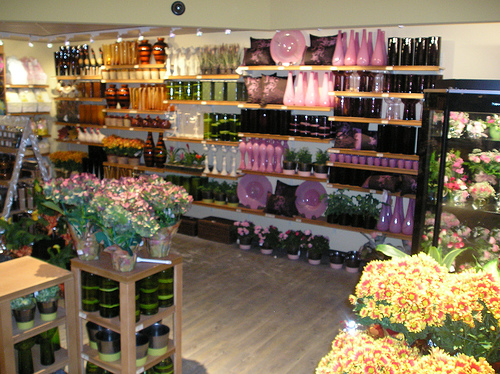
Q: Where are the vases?
A: On the shelves.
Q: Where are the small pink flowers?
A: On the bottom.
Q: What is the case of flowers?
A: Glass.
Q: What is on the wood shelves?
A: Glassware.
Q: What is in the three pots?
A: Plants.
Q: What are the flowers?
A: Red and yellow.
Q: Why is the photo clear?
A: The area is lit.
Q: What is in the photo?
A: Bottles.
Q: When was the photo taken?
A: Nighttime.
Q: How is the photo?
A: Clear.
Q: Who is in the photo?
A: Nobody.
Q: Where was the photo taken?
A: Flower shop.